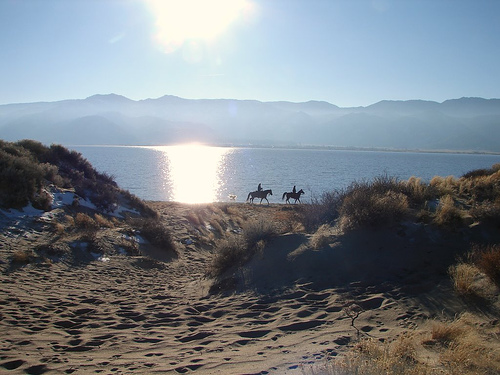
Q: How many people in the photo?
A: Two.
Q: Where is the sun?
A: In the sky.